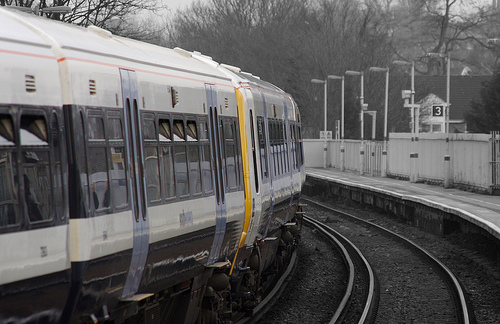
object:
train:
[0, 7, 306, 323]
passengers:
[187, 162, 200, 194]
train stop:
[320, 68, 499, 217]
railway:
[300, 195, 500, 323]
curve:
[237, 252, 302, 323]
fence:
[325, 132, 499, 193]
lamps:
[309, 77, 329, 130]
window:
[159, 117, 175, 199]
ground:
[304, 165, 499, 232]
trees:
[463, 62, 500, 135]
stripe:
[228, 85, 253, 276]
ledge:
[302, 174, 499, 270]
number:
[433, 106, 443, 116]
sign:
[428, 105, 446, 133]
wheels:
[200, 270, 267, 323]